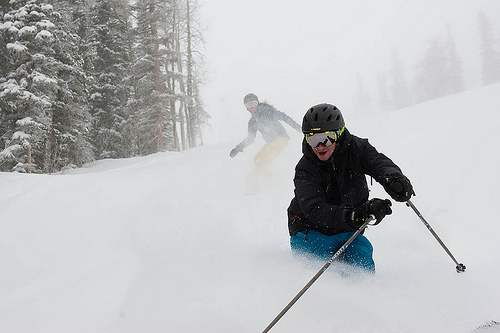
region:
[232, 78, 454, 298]
Two skiiers coming down the mountain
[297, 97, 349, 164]
Skiing with a reflective eye protectant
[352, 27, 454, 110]
Trees in the distance covered in snow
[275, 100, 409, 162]
man has black helmet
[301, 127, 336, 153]
man is wearing goggles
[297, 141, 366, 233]
man has black coat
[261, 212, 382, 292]
man has blue pants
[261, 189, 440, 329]
man holds black poles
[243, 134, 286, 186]
person has yellow pants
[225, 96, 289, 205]
person is on snowboard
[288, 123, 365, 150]
shiny goggles on face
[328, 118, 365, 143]
yellow frames on goggles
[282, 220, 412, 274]
skier wearing blue pants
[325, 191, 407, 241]
ski pole in skier's hand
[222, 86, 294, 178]
skier walking on snow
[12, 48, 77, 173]
tall trees covered with snow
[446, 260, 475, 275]
end of ski pole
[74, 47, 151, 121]
leaves on tall trees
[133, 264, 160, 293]
this is a patch of snow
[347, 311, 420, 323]
this is a patch of snow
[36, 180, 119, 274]
this is a patch of snow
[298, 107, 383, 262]
this is a person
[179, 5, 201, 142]
this is a tree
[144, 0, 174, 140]
this is a tree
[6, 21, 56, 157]
this is a tree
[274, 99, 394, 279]
female skier in white snow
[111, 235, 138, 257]
white snow on hill side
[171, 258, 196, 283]
white snow on hill side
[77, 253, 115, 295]
white snow on hill side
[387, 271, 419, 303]
white snow on hill side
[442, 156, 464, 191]
white snow on hill side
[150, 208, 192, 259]
white snow on hill side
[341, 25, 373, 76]
white clouds in blue sky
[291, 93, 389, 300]
skier in white snow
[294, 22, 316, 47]
white clouds in blue sky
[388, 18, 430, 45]
white clouds in blue sky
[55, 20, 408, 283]
this is on a ski slope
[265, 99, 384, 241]
the person is skiing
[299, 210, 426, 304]
the pants are blue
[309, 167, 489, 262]
the jacket is black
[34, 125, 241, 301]
the snow is deep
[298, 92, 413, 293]
a person is playing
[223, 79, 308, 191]
a person is playing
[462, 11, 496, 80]
a tree in the woods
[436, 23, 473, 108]
a tree in a field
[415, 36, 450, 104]
a tree in a field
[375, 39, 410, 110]
a tree in a field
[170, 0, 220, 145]
a tree in a field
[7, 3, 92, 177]
a tree in a field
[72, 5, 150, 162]
a tree in a field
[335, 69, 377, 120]
a tree in a field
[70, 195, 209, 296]
Large body of snow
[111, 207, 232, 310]
Large body of white snow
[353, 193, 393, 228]
Glove on a hand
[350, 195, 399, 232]
Black glove on a hand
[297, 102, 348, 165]
Helmet on a man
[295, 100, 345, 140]
Black helmet on a man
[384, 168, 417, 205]
Glove on a hand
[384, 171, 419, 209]
Black glove on a hand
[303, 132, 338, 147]
Reflection on a pair of goggles